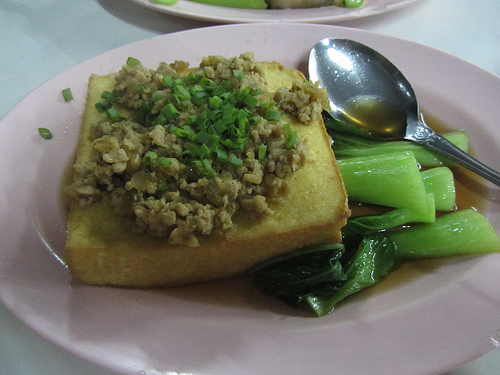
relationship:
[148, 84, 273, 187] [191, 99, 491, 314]
seasoning on top of food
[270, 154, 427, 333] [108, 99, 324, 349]
green vegetable on food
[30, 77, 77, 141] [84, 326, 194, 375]
chives on side of a plate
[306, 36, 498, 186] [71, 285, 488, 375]
spoon on plate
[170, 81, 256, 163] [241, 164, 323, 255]
green garnish on bread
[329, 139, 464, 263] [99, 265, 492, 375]
green vegetables on plate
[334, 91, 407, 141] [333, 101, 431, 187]
liquid on spoon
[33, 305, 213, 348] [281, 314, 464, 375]
shadow of food on plate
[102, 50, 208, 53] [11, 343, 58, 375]
two white plates on table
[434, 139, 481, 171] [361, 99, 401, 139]
handle of silver spoon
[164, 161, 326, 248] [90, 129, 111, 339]
buttered piece of bread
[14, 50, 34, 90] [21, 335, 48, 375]
tablecloth underneath plate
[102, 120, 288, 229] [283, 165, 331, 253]
brown garnish on bread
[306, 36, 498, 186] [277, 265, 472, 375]
spoon on bowl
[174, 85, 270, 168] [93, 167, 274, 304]
green onions sliced on top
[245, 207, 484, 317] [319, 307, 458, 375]
vegetable on plate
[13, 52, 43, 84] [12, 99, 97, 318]
table top under plates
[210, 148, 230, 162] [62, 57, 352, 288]
onion topping bread slice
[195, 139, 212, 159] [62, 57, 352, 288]
onion topping bread slice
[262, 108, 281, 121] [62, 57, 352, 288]
onion topping bread slice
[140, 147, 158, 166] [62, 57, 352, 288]
onion topping bread slice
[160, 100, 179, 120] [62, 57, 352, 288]
onion topping bread slice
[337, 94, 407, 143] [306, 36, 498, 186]
broth lying in spoon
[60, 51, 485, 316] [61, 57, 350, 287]
meal topping bread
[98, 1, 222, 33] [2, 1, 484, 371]
shadow casted on table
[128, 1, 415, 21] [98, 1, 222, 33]
plate casting shadow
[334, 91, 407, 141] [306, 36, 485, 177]
liquid lying in table spoon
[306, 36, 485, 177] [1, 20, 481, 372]
table spoon resting on top of plate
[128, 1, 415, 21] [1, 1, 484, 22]
plate sitting in background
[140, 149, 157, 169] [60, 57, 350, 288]
chive topping meal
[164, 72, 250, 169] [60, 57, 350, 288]
chives topping meal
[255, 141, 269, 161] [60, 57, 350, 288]
chive topping meal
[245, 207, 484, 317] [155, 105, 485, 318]
vegetable lying in juice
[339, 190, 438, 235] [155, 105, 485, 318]
vegetable lying in juice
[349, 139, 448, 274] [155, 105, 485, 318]
vegetables lying in juice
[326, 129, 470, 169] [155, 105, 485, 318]
vegetable lying in juice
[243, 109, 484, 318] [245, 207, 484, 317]
side dish consisting of vegetable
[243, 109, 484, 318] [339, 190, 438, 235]
side dish consisting of vegetable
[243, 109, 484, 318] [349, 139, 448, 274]
side dish consisting of vegetables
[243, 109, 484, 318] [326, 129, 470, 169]
side dish consisting of vegetable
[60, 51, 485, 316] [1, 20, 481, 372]
meal lying on top of plate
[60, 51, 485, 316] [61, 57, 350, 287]
meal consisting of bread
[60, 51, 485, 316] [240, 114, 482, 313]
meal consisting of vegetable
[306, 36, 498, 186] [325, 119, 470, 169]
spoon resting on top of vegetable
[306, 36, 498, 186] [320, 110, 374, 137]
spoon resting on top of vegetable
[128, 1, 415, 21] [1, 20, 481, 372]
plate sitting behind plate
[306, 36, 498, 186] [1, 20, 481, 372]
spoon lying on top of plate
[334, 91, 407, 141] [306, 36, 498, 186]
liquid lying in spoon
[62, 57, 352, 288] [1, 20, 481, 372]
bread slice lying on top of plate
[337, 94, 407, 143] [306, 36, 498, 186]
broth in ladle section of spoon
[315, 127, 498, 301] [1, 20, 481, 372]
broccoli on plate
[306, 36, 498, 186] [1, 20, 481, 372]
spoon on plate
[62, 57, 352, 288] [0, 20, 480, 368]
bread slice on white plate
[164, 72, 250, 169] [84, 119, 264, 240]
chives on top of tuna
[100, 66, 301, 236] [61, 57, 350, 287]
tuna on top of bread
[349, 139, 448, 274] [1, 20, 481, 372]
vegetables on a plate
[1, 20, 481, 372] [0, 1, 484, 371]
plate at bottom of picture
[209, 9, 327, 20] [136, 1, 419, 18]
frame of white plate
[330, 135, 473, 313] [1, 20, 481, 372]
chard on plate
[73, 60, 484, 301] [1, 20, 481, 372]
food on plate